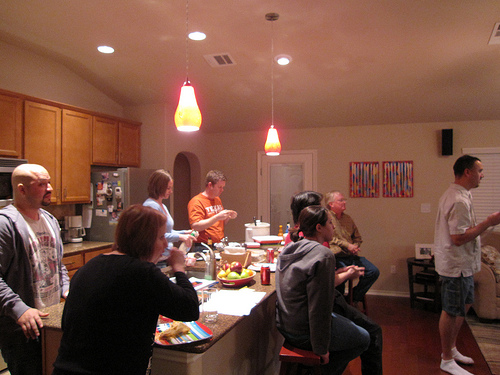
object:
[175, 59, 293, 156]
lamps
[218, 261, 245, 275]
fruits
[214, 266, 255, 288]
bowl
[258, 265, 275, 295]
can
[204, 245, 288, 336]
counter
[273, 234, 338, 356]
jacket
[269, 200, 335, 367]
girl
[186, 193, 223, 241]
tshirt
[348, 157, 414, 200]
paintings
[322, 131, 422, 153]
wall